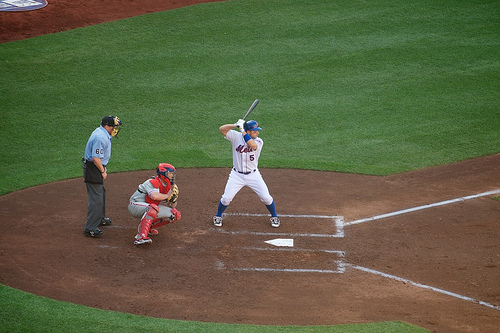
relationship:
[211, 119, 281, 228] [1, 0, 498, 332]
players are on field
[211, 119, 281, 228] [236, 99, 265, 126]
players are holding bat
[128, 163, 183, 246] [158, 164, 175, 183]
catcher wearing mask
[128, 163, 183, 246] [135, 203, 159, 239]
catcher wearing shin guards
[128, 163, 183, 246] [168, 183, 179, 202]
catcher wearing glove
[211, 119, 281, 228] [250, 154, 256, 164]
players wear number 5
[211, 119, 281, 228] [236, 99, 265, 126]
players are swinging bat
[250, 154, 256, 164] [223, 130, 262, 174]
number 5 on jersey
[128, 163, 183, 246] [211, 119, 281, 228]
catcher behind players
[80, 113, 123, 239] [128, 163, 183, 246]
umpire behind catcher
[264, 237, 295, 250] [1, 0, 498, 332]
home plate of field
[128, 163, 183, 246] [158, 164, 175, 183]
catcher has mask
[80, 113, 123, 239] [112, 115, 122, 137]
umpire has mask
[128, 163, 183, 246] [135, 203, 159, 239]
catcher has shin guards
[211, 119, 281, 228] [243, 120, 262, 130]
players have helmet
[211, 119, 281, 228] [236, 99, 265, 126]
players have bat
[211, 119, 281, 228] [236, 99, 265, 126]
players ready to swing bat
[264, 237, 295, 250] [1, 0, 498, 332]
home plate on field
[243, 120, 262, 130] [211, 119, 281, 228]
helmet on players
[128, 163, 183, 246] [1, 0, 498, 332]
catcher on field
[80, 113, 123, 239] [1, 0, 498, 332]
umpire on field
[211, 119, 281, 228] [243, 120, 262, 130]
players has helmet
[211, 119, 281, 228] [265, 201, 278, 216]
players have socks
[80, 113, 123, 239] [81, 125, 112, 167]
umpire has shirt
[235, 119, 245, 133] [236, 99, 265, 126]
hands swinging bat